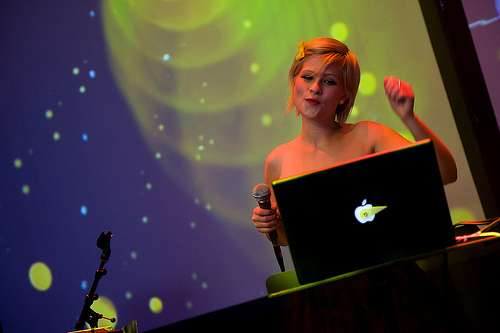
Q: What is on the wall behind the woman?
A: Projected lights.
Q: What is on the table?
A: Laptop computer.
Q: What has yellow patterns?
A: Blue backlit wall.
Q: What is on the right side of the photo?
A: Back desk with computer on top of it.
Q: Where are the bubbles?
A: On a screen.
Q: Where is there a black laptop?
A: On a table.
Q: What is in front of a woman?
A: Black laptop.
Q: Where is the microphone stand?
A: Next to a woman.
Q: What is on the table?
A: Laptop.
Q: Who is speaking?
A: A woman.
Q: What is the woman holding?
A: A mic.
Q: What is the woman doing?
A: A presentation.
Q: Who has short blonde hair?
A: The girl.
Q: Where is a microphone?
A: In girl's right hand.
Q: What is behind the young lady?
A: Big screen.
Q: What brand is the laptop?
A: Apple.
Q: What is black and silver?
A: Microphone.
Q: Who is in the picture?
A: One.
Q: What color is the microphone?
A: Silver and black.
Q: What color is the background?
A: Purple and green.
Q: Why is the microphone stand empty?
A: The woman is holding the microphone.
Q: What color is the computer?
A: Black.